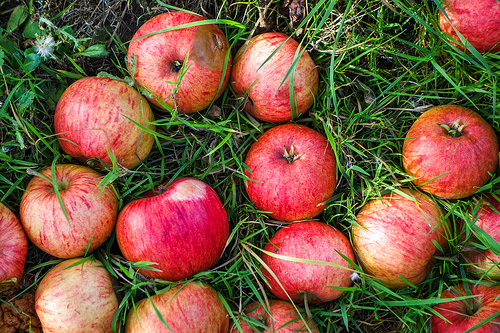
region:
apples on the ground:
[61, 37, 437, 319]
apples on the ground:
[27, 11, 432, 300]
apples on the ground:
[48, 59, 438, 323]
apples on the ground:
[40, 81, 397, 324]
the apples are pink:
[112, 159, 228, 284]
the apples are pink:
[77, 156, 254, 287]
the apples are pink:
[97, 179, 274, 306]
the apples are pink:
[97, 172, 266, 328]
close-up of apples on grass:
[11, 10, 486, 320]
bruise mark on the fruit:
[190, 15, 230, 65]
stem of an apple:
[25, 162, 61, 192]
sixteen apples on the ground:
[11, 9, 492, 315]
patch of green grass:
[340, 25, 415, 105]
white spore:
[26, 25, 56, 60]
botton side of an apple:
[270, 135, 315, 180]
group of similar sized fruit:
[10, 5, 410, 291]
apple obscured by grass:
[450, 191, 495, 272]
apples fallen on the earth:
[7, 6, 488, 329]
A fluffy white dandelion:
[31, 36, 58, 58]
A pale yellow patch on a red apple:
[178, 179, 205, 201]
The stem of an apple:
[172, 54, 184, 73]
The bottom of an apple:
[283, 143, 302, 164]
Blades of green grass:
[371, 283, 421, 312]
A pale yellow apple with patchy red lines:
[58, 280, 101, 310]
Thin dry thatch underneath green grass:
[335, 18, 364, 50]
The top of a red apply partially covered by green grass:
[440, 279, 493, 326]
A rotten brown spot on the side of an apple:
[186, 22, 231, 71]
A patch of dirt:
[7, 302, 32, 332]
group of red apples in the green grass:
[30, 7, 489, 320]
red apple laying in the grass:
[126, 4, 231, 117]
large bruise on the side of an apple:
[192, 25, 230, 72]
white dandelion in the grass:
[27, 26, 69, 63]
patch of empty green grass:
[327, 30, 449, 120]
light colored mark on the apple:
[164, 180, 213, 211]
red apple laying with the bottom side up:
[396, 93, 498, 203]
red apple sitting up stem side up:
[16, 153, 121, 252]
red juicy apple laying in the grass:
[222, 125, 351, 223]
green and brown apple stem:
[21, 168, 73, 192]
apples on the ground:
[232, 31, 323, 119]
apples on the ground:
[238, 122, 338, 214]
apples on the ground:
[118, 175, 235, 282]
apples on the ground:
[21, 160, 113, 254]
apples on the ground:
[44, 73, 160, 160]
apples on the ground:
[401, 103, 493, 200]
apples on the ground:
[38, 261, 110, 331]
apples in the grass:
[11, 152, 116, 264]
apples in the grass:
[225, 123, 340, 217]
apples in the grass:
[52, 66, 153, 165]